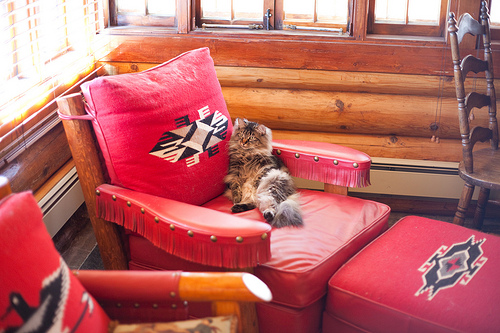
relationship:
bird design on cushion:
[1, 259, 99, 330] [0, 191, 120, 331]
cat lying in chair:
[235, 119, 295, 221] [69, 52, 399, 331]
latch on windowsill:
[263, 13, 274, 33] [202, 2, 265, 37]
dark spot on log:
[333, 97, 345, 114] [221, 89, 498, 144]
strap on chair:
[66, 106, 97, 124] [54, 90, 390, 333]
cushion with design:
[78, 46, 233, 206] [149, 108, 232, 166]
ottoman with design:
[322, 211, 499, 329] [412, 226, 492, 302]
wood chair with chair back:
[440, 2, 498, 231] [446, 0, 497, 171]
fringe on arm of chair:
[92, 175, 279, 275] [50, 49, 392, 303]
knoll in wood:
[309, 71, 384, 91] [261, 62, 465, 146]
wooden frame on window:
[364, 0, 443, 41] [380, 0, 434, 20]